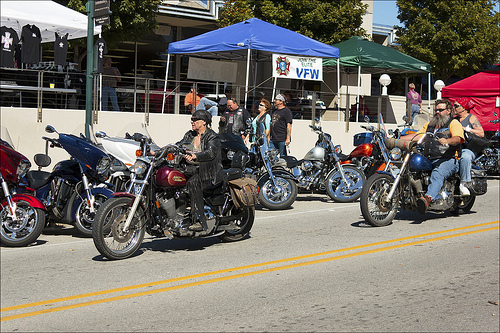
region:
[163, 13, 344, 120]
a blue awning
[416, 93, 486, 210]
two men on bike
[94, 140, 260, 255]
a burgundy trimmed bike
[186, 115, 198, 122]
a pair of black shades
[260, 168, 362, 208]
blue wheels on bike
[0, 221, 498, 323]
yellow lines on bike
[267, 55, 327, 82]
a blue and white banner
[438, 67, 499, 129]
a red tent to right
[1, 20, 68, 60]
shirts hanging under tent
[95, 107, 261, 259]
a man riding bike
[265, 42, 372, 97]
short text written in board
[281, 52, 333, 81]
a blue words in board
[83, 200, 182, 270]
wheel of the bike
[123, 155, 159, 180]
front light of the bike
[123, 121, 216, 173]
handle of the bike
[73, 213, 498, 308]
a line in road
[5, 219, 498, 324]
two yellow lines in road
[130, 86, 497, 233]
a group of people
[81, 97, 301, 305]
a man driving the bike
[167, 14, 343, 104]
a big blue umbrella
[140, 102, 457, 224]
two men riding motorcycles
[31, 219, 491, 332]
yellow lines painted on a road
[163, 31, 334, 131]
a blue canopy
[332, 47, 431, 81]
a green canopy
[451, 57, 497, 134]
a red tent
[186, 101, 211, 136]
a man wearing sunglasses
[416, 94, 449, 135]
a man with a long beard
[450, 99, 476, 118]
a woman wearing a red bandana on her head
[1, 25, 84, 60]
black shirts hanging under a canopy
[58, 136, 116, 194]
a blue motorcycle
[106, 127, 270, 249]
Bike parked on pavement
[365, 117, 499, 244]
Bike parked on pavement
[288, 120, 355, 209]
Bike parked on pavement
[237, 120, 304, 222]
Bike parked on pavement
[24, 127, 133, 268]
Bike parked on pavement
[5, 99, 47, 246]
Bike parked on pavement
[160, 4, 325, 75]
Light blue canopy on sidewalk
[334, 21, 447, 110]
Green canopy on sidewalk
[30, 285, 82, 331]
Yellow lines on pavement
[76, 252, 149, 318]
Yellow lines on pavement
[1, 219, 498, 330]
two solid yellow lines on the road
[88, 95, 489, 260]
bikers on the road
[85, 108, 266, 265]
a guy riding his big bike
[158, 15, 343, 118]
a blue canopy tent on the sidewalk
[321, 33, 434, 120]
a green canopy tent on the sidewalk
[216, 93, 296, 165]
people walking on the sidewalk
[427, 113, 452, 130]
a beard of the guy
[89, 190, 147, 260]
a front wheel of the motorcycle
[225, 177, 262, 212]
a bag attached to the motorcycle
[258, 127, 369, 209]
motorcycles parked in the sidewalk